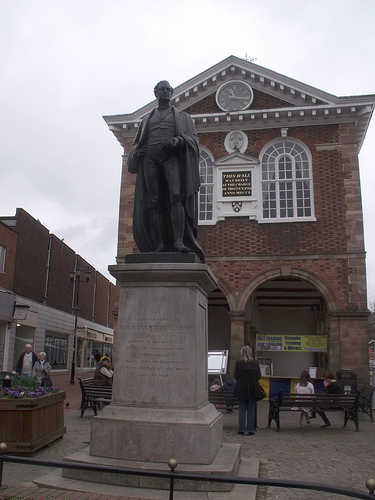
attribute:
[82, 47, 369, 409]
building — brick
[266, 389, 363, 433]
bench — metal, wood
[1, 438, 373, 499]
railing — metal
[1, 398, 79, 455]
container — large, square, wood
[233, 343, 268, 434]
woman — blonde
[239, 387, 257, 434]
jeans — blue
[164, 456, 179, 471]
top — gold, round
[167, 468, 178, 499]
post — fence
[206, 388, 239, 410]
bench — brown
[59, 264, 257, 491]
monument — stone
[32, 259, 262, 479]
pedestal — concrete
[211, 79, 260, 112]
clock — round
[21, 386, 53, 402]
flower — purple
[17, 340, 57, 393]
couple — eldery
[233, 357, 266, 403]
coat — black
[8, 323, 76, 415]
couple — old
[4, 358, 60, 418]
flowers — purple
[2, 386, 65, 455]
flower box — wooden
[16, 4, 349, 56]
sky — overcast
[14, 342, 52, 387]
couple — old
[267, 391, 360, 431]
bench — brown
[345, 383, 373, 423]
bench — brown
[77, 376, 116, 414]
bench — brown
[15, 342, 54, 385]
couple — older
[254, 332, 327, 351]
banner — yellow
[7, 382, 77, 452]
bed — flower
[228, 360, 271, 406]
jacket — black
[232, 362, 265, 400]
coat — black